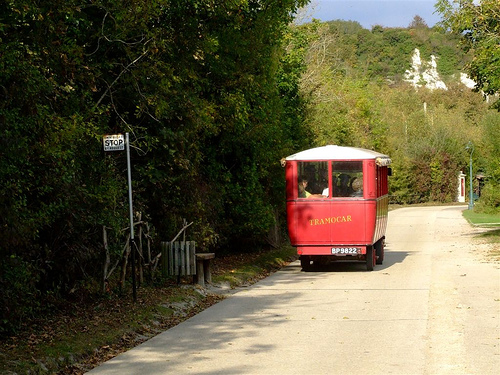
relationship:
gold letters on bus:
[304, 210, 354, 227] [282, 144, 394, 271]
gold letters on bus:
[306, 201, 352, 237] [282, 144, 394, 271]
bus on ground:
[282, 144, 394, 271] [0, 206, 500, 375]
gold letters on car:
[304, 210, 354, 227] [268, 135, 405, 295]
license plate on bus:
[331, 245, 363, 255] [282, 144, 394, 271]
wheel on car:
[363, 242, 378, 271] [276, 144, 394, 270]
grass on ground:
[38, 277, 243, 372] [42, 291, 168, 346]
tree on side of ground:
[51, 3, 270, 260] [0, 206, 500, 375]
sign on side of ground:
[105, 131, 130, 149] [0, 206, 500, 375]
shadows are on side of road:
[187, 282, 262, 353] [276, 281, 440, 349]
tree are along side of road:
[0, 3, 270, 314] [138, 222, 465, 372]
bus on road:
[282, 144, 394, 271] [404, 207, 483, 349]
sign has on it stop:
[104, 131, 129, 152] [106, 140, 129, 147]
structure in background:
[405, 45, 425, 93] [309, 6, 492, 60]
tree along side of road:
[0, 3, 270, 314] [131, 209, 492, 364]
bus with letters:
[282, 144, 394, 271] [298, 211, 353, 228]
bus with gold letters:
[282, 144, 394, 271] [304, 210, 354, 227]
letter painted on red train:
[309, 217, 315, 226] [272, 126, 405, 302]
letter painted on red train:
[312, 217, 319, 225] [272, 126, 405, 302]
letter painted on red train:
[317, 217, 324, 225] [272, 126, 405, 302]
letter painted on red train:
[330, 216, 337, 225] [272, 126, 405, 302]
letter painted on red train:
[345, 214, 352, 222] [272, 126, 405, 302]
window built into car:
[316, 145, 403, 230] [276, 144, 394, 270]